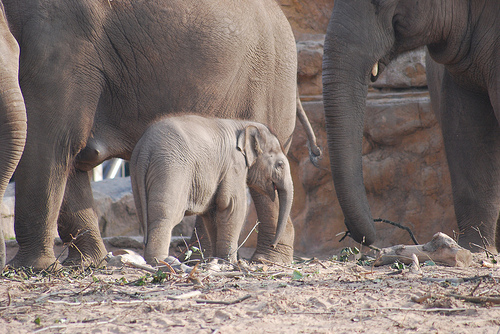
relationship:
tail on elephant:
[293, 91, 324, 163] [155, 130, 339, 277]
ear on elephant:
[230, 127, 271, 166] [127, 115, 294, 270]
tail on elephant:
[293, 91, 324, 163] [2, 2, 317, 272]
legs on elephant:
[13, 100, 111, 270] [430, 53, 499, 254]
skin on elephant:
[114, 5, 281, 111] [320, 0, 499, 256]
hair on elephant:
[149, 110, 221, 123] [130, 110, 292, 261]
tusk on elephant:
[360, 58, 381, 87] [329, 3, 499, 245]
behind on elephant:
[132, 119, 172, 188] [138, 112, 340, 262]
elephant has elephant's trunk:
[127, 115, 294, 270] [264, 170, 294, 254]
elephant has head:
[320, 0, 499, 256] [345, 3, 493, 58]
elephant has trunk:
[320, 0, 499, 256] [315, 63, 387, 253]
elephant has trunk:
[320, 0, 499, 256] [322, 69, 389, 246]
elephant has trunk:
[320, 0, 499, 256] [323, 2, 378, 244]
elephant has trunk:
[127, 115, 294, 270] [121, 99, 299, 279]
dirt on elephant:
[166, 141, 231, 181] [111, 104, 302, 261]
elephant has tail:
[127, 115, 294, 270] [133, 152, 158, 255]